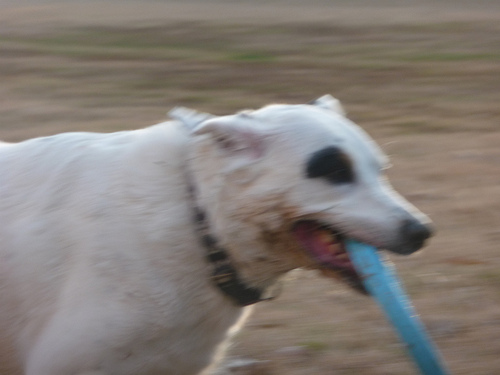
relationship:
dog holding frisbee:
[0, 93, 433, 375] [303, 204, 453, 375]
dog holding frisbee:
[0, 93, 433, 375] [294, 222, 460, 375]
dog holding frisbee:
[86, 99, 370, 289] [323, 244, 438, 331]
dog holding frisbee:
[0, 93, 433, 375] [279, 252, 449, 373]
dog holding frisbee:
[0, 93, 433, 375] [316, 278, 428, 346]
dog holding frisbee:
[0, 93, 433, 375] [272, 235, 452, 337]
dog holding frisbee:
[0, 93, 433, 375] [304, 234, 444, 364]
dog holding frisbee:
[0, 93, 433, 375] [322, 266, 459, 375]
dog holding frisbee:
[0, 93, 433, 375] [314, 230, 457, 347]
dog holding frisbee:
[0, 93, 433, 375] [332, 273, 430, 375]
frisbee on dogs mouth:
[362, 247, 442, 287] [274, 201, 430, 373]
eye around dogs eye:
[301, 143, 355, 191] [259, 100, 409, 237]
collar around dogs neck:
[170, 169, 230, 280] [173, 212, 270, 282]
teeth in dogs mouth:
[246, 194, 380, 314] [310, 205, 420, 265]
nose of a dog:
[403, 213, 423, 242] [86, 308, 156, 369]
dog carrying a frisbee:
[0, 93, 433, 375] [292, 214, 443, 375]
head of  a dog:
[185, 95, 434, 300] [54, 245, 252, 354]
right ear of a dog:
[194, 151, 283, 225] [21, 173, 314, 334]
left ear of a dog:
[303, 98, 365, 113] [54, 238, 252, 372]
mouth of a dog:
[292, 205, 442, 305] [106, 134, 303, 323]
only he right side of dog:
[17, 212, 231, 375] [12, 165, 342, 319]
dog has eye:
[0, 93, 433, 375] [301, 143, 355, 191]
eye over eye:
[301, 143, 355, 191] [316, 150, 346, 171]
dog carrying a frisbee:
[0, 93, 433, 375] [346, 232, 436, 364]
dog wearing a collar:
[0, 93, 433, 375] [168, 142, 248, 291]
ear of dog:
[189, 107, 265, 156] [0, 93, 433, 375]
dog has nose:
[0, 93, 433, 375] [393, 202, 441, 258]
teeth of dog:
[297, 219, 363, 269] [72, 57, 428, 370]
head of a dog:
[211, 71, 456, 371] [0, 93, 433, 375]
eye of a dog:
[297, 142, 355, 191] [100, 43, 467, 357]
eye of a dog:
[301, 143, 355, 191] [66, 32, 414, 359]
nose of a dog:
[403, 213, 438, 249] [92, 39, 439, 370]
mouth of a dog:
[300, 205, 442, 305] [0, 93, 433, 375]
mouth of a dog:
[292, 205, 442, 305] [118, 38, 449, 368]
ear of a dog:
[189, 111, 265, 155] [75, 22, 455, 367]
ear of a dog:
[189, 111, 265, 155] [0, 93, 433, 375]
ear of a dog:
[189, 111, 265, 155] [118, 38, 449, 368]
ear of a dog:
[312, 85, 355, 133] [127, 50, 439, 351]